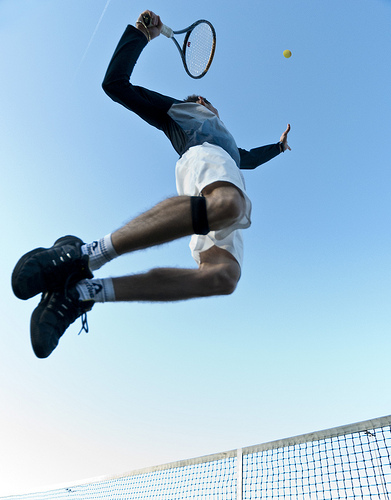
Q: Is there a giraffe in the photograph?
A: No, there are no giraffes.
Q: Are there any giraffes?
A: No, there are no giraffes.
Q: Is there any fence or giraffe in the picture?
A: No, there are no giraffes or fences.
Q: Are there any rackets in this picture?
A: Yes, there is a racket.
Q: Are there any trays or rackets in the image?
A: Yes, there is a racket.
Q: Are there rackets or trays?
A: Yes, there is a racket.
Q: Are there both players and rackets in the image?
A: Yes, there are both a racket and a player.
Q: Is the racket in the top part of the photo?
A: Yes, the racket is in the top of the image.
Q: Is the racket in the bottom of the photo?
A: No, the racket is in the top of the image.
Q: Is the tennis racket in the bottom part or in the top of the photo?
A: The tennis racket is in the top of the image.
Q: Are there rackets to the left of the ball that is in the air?
A: Yes, there is a racket to the left of the ball.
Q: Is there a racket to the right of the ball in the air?
A: No, the racket is to the left of the ball.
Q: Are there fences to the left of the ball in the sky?
A: No, there is a racket to the left of the ball.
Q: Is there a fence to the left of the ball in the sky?
A: No, there is a racket to the left of the ball.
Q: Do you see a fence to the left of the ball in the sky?
A: No, there is a racket to the left of the ball.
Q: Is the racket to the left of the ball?
A: Yes, the racket is to the left of the ball.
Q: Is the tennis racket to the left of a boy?
A: No, the tennis racket is to the left of the ball.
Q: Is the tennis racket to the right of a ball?
A: No, the tennis racket is to the left of a ball.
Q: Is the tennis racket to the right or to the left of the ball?
A: The tennis racket is to the left of the ball.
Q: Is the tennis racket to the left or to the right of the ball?
A: The tennis racket is to the left of the ball.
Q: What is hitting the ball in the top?
A: The tennis racket is hitting the ball.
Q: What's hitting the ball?
A: The tennis racket is hitting the ball.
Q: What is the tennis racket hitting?
A: The tennis racket is hitting the ball.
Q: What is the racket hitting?
A: The tennis racket is hitting the ball.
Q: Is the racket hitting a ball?
A: Yes, the racket is hitting a ball.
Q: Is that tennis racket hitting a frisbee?
A: No, the tennis racket is hitting a ball.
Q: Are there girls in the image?
A: No, there are no girls.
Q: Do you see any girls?
A: No, there are no girls.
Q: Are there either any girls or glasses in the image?
A: No, there are no girls or glasses.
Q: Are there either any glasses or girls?
A: No, there are no girls or glasses.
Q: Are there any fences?
A: No, there are no fences.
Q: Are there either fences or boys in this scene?
A: No, there are no fences or boys.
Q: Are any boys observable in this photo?
A: No, there are no boys.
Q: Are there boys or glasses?
A: No, there are no boys or glasses.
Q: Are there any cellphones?
A: No, there are no cellphones.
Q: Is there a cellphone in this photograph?
A: No, there are no cell phones.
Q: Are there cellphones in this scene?
A: No, there are no cellphones.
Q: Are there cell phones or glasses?
A: No, there are no cell phones or glasses.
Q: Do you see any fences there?
A: No, there are no fences.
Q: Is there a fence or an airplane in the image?
A: No, there are no fences or airplanes.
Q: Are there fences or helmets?
A: No, there are no fences or helmets.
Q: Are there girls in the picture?
A: No, there are no girls.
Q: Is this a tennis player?
A: Yes, this is a tennis player.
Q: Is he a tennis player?
A: Yes, this is a tennis player.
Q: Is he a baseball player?
A: No, this is a tennis player.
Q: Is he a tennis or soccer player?
A: This is a tennis player.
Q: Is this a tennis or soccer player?
A: This is a tennis player.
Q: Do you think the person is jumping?
A: Yes, the player is jumping.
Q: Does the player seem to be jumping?
A: Yes, the player is jumping.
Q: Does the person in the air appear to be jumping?
A: Yes, the player is jumping.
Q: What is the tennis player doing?
A: The player is jumping.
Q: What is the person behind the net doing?
A: The player is jumping.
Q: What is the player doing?
A: The player is jumping.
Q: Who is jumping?
A: The player is jumping.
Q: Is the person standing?
A: No, the player is jumping.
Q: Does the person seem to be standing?
A: No, the player is jumping.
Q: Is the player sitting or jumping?
A: The player is jumping.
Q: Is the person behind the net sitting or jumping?
A: The player is jumping.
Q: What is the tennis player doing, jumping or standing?
A: The player is jumping.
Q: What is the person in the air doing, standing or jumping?
A: The player is jumping.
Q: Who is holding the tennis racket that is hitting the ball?
A: The player is holding the tennis racket.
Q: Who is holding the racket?
A: The player is holding the tennis racket.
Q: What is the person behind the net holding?
A: The player is holding the racket.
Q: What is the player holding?
A: The player is holding the racket.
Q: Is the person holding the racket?
A: Yes, the player is holding the racket.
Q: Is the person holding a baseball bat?
A: No, the player is holding the racket.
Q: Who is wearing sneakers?
A: The player is wearing sneakers.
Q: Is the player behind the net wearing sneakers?
A: Yes, the player is wearing sneakers.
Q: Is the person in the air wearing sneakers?
A: Yes, the player is wearing sneakers.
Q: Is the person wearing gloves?
A: No, the player is wearing sneakers.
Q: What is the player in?
A: The player is in the air.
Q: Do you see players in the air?
A: Yes, there is a player in the air.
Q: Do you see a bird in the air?
A: No, there is a player in the air.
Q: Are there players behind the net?
A: Yes, there is a player behind the net.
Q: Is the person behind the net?
A: Yes, the player is behind the net.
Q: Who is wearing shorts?
A: The player is wearing shorts.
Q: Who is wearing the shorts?
A: The player is wearing shorts.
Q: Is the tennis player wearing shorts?
A: Yes, the player is wearing shorts.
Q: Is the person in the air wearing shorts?
A: Yes, the player is wearing shorts.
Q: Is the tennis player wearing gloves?
A: No, the player is wearing shorts.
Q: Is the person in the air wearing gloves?
A: No, the player is wearing shorts.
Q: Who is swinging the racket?
A: The player is swinging the racket.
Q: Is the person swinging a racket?
A: Yes, the player is swinging a racket.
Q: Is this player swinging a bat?
A: No, the player is swinging a racket.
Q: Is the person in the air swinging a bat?
A: No, the player is swinging a racket.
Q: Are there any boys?
A: No, there are no boys.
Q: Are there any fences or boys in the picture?
A: No, there are no boys or fences.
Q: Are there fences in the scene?
A: No, there are no fences.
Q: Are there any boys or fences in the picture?
A: No, there are no fences or boys.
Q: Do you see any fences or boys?
A: No, there are no fences or boys.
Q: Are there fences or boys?
A: No, there are no fences or boys.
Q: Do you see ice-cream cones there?
A: No, there are no ice-cream cones.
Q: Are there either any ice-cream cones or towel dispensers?
A: No, there are no ice-cream cones or towel dispensers.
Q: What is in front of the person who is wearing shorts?
A: The net is in front of the player.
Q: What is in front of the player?
A: The net is in front of the player.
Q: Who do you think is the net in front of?
A: The net is in front of the player.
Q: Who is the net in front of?
A: The net is in front of the player.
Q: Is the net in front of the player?
A: Yes, the net is in front of the player.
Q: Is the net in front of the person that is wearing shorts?
A: Yes, the net is in front of the player.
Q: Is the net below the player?
A: Yes, the net is below the player.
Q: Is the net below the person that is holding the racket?
A: Yes, the net is below the player.